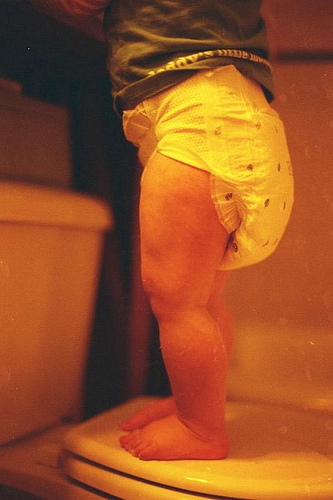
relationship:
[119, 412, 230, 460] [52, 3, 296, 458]
baby's foot of baby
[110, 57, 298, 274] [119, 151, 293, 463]
diaper on baby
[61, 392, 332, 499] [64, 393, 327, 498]
lid of toilet seat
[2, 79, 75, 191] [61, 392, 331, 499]
tissue box on toilet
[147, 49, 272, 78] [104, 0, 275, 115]
writing on tshirt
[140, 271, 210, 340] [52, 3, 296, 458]
knee on baby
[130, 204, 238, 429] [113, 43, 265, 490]
legs of toddler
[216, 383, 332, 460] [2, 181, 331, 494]
shadow on toilet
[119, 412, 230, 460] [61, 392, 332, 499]
baby's foot on lid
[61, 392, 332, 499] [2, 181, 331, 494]
lid on toilet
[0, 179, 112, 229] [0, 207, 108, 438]
lid of tank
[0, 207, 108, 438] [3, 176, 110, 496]
tank on toilet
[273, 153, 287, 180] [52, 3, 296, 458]
pattern of baby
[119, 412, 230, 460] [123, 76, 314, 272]
baby's foot wears diaper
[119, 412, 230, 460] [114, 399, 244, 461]
baby's foot has feet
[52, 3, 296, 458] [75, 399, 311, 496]
baby on board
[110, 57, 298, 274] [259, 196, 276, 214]
diaper has pattern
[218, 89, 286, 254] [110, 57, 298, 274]
pattern on diaper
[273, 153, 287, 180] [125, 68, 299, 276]
pattern on diaper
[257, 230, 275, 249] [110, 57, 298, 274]
pattern on diaper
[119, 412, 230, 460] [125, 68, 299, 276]
baby's foot wearing diaper